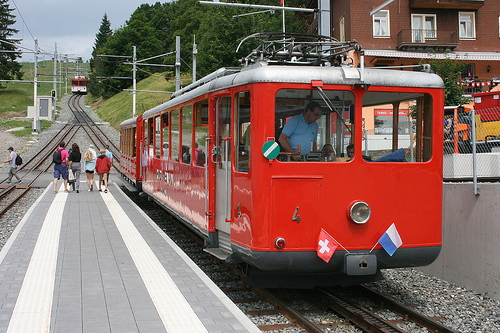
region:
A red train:
[113, 17, 430, 299]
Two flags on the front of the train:
[309, 210, 401, 282]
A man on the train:
[265, 97, 340, 170]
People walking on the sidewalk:
[30, 142, 128, 197]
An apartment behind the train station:
[347, 4, 484, 77]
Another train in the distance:
[48, 61, 90, 142]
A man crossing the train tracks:
[0, 144, 23, 185]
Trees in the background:
[69, 3, 204, 105]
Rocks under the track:
[400, 272, 457, 318]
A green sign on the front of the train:
[252, 131, 281, 170]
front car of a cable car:
[142, 58, 443, 265]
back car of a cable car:
[119, 114, 141, 192]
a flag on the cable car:
[308, 226, 359, 275]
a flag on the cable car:
[363, 221, 403, 261]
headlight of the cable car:
[347, 194, 375, 231]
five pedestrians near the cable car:
[49, 139, 116, 199]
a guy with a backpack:
[46, 136, 70, 203]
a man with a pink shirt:
[50, 140, 70, 197]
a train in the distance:
[67, 72, 91, 94]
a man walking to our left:
[0, 141, 27, 191]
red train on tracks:
[100, 44, 498, 315]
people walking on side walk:
[38, 135, 135, 215]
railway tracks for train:
[235, 275, 480, 331]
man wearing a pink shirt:
[50, 133, 70, 198]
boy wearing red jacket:
[87, 137, 125, 205]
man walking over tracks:
[3, 136, 26, 202]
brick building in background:
[315, 0, 499, 91]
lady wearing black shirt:
[60, 138, 95, 203]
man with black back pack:
[44, 131, 77, 206]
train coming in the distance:
[62, 47, 101, 130]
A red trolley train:
[101, 16, 464, 298]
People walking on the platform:
[26, 122, 147, 222]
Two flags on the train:
[308, 211, 424, 291]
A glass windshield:
[261, 78, 443, 173]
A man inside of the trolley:
[274, 99, 354, 169]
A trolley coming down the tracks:
[53, 59, 138, 161]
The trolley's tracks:
[41, 97, 124, 158]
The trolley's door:
[210, 74, 245, 269]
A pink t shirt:
[51, 144, 73, 169]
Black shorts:
[74, 163, 105, 185]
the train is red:
[169, 106, 453, 251]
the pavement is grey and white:
[23, 211, 179, 324]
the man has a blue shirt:
[280, 119, 333, 153]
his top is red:
[96, 159, 123, 186]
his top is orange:
[51, 148, 77, 171]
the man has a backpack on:
[3, 152, 38, 174]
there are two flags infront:
[305, 211, 453, 282]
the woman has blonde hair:
[78, 142, 102, 181]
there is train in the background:
[63, 63, 105, 107]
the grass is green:
[107, 98, 166, 122]